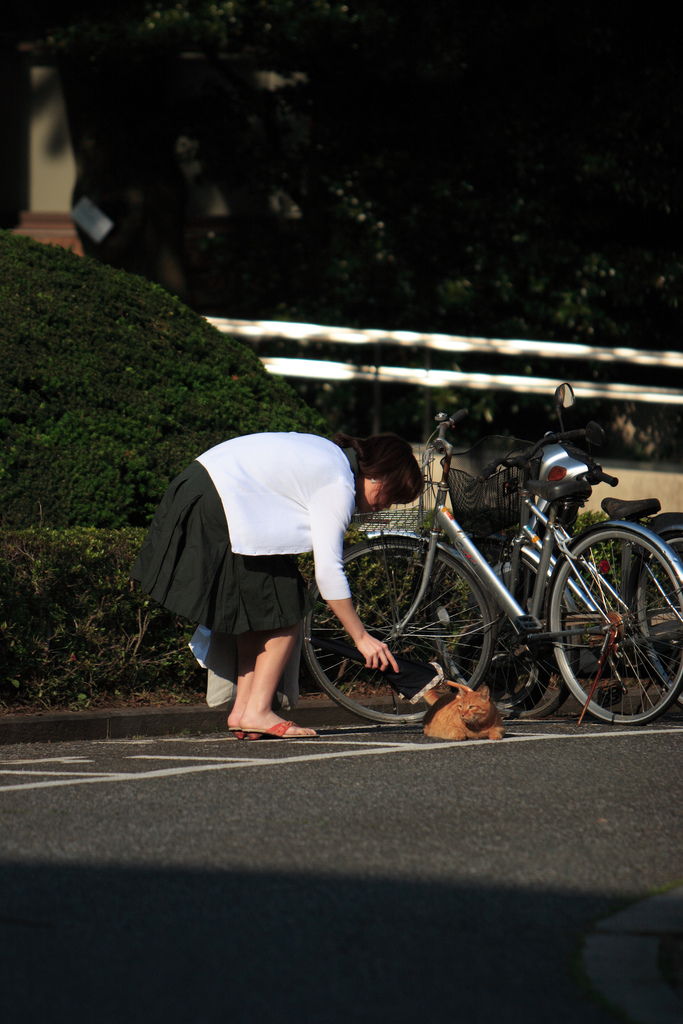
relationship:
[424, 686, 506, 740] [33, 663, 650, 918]
cat laying on top of ground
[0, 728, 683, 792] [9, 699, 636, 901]
lines are on top of ground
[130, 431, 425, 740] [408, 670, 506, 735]
woman touching cat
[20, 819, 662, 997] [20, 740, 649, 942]
shadow on top of ground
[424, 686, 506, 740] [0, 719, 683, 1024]
cat on ground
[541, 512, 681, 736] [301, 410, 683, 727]
wheel on bicycle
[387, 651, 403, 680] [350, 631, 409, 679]
finger on hand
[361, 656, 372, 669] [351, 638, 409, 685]
finger on hand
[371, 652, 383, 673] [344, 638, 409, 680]
finger on hand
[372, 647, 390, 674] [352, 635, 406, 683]
finger on hand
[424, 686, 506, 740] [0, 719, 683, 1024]
cat laying on ground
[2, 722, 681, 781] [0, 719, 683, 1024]
lines on ground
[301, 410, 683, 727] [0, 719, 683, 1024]
bicycle on ground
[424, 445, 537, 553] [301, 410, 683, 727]
bag on bicycle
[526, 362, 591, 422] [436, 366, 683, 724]
mirror on bicycle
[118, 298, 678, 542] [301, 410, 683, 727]
road behind bicycle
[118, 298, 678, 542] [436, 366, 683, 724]
road behind bicycle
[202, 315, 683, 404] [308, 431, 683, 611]
fence along road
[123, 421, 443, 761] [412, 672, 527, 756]
woman touching cat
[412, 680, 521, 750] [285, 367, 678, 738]
cat in front of bicycle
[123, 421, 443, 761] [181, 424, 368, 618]
woman wearing cardigan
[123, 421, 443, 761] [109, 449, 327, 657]
woman wearing skirt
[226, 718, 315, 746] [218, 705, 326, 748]
sandals on feet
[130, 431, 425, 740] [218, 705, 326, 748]
woman has feet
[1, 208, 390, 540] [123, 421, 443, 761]
bush behind woman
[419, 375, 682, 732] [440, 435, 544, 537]
bicycle has bag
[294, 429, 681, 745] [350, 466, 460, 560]
bicycle has basket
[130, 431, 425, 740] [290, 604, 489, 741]
woman holding umbrella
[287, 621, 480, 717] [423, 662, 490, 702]
umbrella has handle